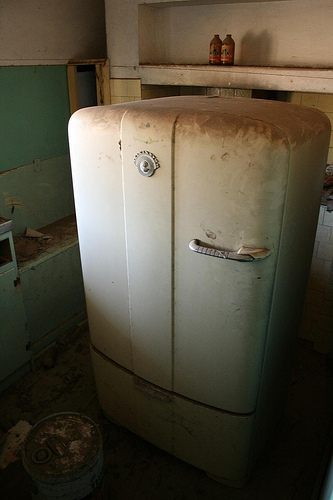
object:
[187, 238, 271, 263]
handle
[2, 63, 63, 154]
wall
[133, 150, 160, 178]
logo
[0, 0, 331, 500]
kitchen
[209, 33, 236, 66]
botttles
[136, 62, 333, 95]
shelf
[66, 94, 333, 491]
chest